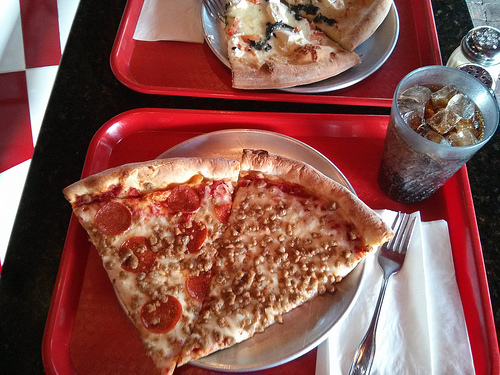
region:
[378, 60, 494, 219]
A soft drink with ice.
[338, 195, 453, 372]
A fork and napkin.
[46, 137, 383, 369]
Two big slices.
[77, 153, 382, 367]
One with pepperoni and one without.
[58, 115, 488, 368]
Food on a red tray.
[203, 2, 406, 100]
Two slices of spinach pizza.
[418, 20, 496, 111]
Cheese and pepper shakers.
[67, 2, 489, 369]
A place setting for two people.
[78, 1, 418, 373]
Four big slices of pizza.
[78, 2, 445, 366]
Looks like a full meal.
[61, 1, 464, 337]
two red trays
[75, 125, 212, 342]
a slice of pepperoni pizza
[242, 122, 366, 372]
slice of pizza on a white plate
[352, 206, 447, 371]
fork on a white napkin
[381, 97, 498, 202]
a soft drink with ice cubes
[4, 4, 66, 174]
checkered white and red linoleum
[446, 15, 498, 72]
tip of a salt shaker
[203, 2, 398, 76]
two slices of thin pizza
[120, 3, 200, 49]
a white paper napkin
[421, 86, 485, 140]
ice cubes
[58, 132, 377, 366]
Two different slices of pizza.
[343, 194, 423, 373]
A fork for eating.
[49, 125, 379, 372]
One slice is as large as the plate.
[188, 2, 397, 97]
Looks like spinach pizza.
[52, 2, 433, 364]
Four slices and three kinds of pizza.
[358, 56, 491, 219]
A drink with ice.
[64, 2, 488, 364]
Two red trays.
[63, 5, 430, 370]
A nice meal.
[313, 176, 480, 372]
Napkins for cleaning.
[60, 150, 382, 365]
two slices of pizza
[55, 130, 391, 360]
pizza is on plate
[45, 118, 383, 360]
plate is silver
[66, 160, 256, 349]
pepperoni on pizza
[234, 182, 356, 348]
sausage crumbles on pizza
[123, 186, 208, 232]
red sauce on pizza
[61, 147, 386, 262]
pizza crust is brown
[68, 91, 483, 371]
fork on tray next to pizza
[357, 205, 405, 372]
fork is silver in color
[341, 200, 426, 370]
napkins under fork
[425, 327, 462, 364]
part of a tissue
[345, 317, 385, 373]
part of a handle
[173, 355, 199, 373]
tip of a pizza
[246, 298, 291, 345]
edge of a pizza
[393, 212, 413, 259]
part of a fork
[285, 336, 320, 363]
edge of a plate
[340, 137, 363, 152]
part of a tray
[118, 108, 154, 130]
edge of a tray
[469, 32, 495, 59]
top of a salt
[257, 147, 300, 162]
part of a pizza